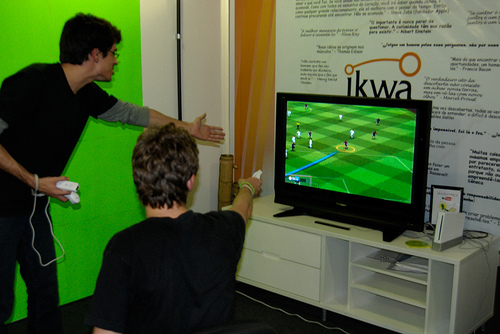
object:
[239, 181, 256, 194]
wristband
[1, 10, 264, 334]
man man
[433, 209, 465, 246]
wii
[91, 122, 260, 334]
man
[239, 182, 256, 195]
bracelet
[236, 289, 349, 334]
white cord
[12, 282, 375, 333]
floor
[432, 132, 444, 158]
ground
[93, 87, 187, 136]
arm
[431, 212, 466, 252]
console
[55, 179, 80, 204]
controller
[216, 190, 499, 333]
stand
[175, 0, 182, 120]
cord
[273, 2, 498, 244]
wall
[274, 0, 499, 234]
writing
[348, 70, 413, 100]
letters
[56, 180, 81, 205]
green apple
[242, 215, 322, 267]
drawer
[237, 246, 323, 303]
drawer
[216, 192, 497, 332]
table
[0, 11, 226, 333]
man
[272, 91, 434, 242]
television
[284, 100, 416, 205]
screen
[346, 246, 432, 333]
shelves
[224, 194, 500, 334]
desk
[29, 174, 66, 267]
wire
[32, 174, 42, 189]
wrist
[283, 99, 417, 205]
video game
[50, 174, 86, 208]
game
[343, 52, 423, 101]
logo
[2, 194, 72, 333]
pants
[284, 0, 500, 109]
words